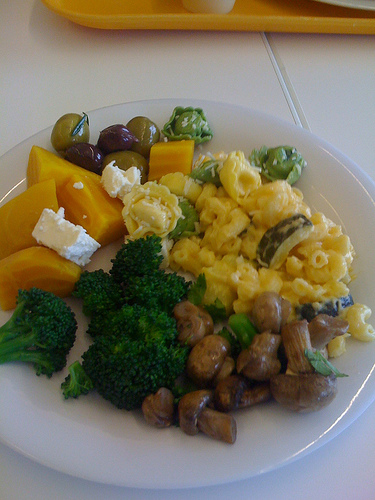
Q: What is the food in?
A: Plate.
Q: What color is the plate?
A: White.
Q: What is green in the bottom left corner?
A: Broccoli.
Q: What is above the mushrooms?
A: Macaroni noodles.